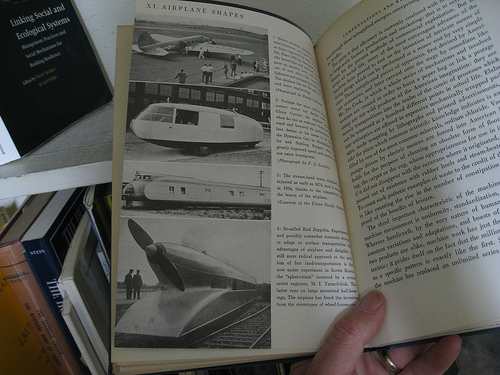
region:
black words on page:
[378, 174, 467, 219]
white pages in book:
[97, 175, 390, 322]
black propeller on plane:
[124, 212, 164, 274]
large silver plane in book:
[147, 242, 264, 304]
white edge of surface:
[27, 147, 93, 206]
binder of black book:
[15, 223, 70, 297]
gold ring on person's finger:
[371, 347, 412, 365]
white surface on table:
[49, 135, 131, 151]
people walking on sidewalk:
[165, 55, 280, 97]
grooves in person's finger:
[310, 301, 385, 343]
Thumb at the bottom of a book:
[309, 287, 393, 374]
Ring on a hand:
[377, 346, 401, 373]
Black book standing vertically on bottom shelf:
[21, 189, 121, 374]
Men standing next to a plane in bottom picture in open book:
[120, 266, 150, 301]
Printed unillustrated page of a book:
[312, 0, 498, 350]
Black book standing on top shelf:
[0, 0, 113, 165]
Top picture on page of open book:
[128, 13, 271, 91]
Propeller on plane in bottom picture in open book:
[125, 216, 190, 293]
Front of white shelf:
[1, 163, 111, 197]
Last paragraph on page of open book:
[272, 223, 363, 309]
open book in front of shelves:
[25, 20, 488, 358]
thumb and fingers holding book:
[206, 285, 481, 367]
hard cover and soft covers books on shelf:
[7, 200, 102, 365]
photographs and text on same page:
[105, 0, 350, 346]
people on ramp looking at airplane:
[135, 20, 270, 90]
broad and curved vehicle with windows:
[122, 91, 267, 158]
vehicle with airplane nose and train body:
[116, 165, 271, 220]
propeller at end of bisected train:
[115, 212, 265, 337]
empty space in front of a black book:
[15, 20, 110, 157]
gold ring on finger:
[301, 325, 462, 370]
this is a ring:
[383, 355, 399, 371]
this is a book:
[215, 32, 499, 272]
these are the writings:
[281, 224, 346, 303]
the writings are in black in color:
[281, 242, 333, 282]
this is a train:
[141, 170, 256, 207]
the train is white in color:
[183, 182, 205, 190]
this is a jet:
[153, 26, 239, 58]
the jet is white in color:
[151, 42, 168, 50]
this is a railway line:
[233, 315, 270, 342]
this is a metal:
[246, 332, 275, 342]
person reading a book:
[101, 31, 469, 374]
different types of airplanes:
[118, 3, 298, 352]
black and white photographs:
[124, 18, 281, 355]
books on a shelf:
[5, 14, 111, 374]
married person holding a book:
[265, 153, 472, 373]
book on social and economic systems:
[3, 3, 104, 137]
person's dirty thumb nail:
[293, 246, 410, 373]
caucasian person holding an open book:
[267, 223, 466, 374]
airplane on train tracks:
[115, 208, 275, 353]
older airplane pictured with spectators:
[127, 16, 276, 92]